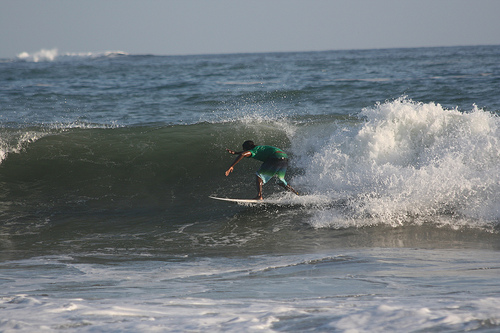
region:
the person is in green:
[232, 137, 306, 199]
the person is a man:
[230, 130, 310, 192]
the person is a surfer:
[227, 136, 339, 206]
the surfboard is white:
[220, 190, 352, 215]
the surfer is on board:
[214, 127, 359, 224]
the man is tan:
[225, 135, 299, 203]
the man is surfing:
[215, 134, 337, 217]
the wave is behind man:
[80, 122, 462, 245]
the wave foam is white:
[283, 120, 485, 225]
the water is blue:
[121, 59, 431, 129]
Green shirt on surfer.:
[243, 147, 288, 163]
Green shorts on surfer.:
[254, 157, 291, 179]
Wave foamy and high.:
[322, 97, 499, 237]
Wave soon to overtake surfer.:
[14, 125, 296, 198]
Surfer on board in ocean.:
[217, 141, 303, 200]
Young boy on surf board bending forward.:
[217, 140, 306, 197]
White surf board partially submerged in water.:
[210, 193, 348, 205]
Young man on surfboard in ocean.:
[204, 137, 349, 221]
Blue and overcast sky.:
[106, 5, 471, 36]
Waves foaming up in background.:
[18, 49, 58, 62]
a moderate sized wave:
[12, 107, 397, 234]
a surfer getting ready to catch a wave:
[202, 123, 340, 231]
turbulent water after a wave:
[282, 86, 498, 237]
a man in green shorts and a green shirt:
[207, 127, 307, 217]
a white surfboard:
[200, 183, 360, 220]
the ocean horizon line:
[26, 26, 498, 73]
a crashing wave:
[110, 78, 495, 238]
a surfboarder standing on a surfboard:
[191, 115, 342, 220]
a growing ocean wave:
[9, 98, 215, 268]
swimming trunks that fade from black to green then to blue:
[250, 148, 304, 188]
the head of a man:
[238, 133, 259, 157]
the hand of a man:
[220, 162, 234, 179]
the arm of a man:
[228, 150, 256, 175]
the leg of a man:
[252, 157, 281, 201]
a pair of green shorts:
[248, 150, 291, 187]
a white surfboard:
[207, 191, 325, 211]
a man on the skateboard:
[218, 132, 306, 208]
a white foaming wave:
[279, 85, 498, 239]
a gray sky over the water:
[0, 0, 497, 65]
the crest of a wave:
[0, 85, 499, 147]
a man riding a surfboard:
[208, 137, 306, 210]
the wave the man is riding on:
[6, 123, 499, 238]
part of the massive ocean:
[13, 250, 498, 330]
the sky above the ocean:
[1, 0, 496, 50]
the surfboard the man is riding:
[207, 187, 252, 202]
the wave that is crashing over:
[290, 105, 475, 215]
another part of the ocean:
[2, 51, 492, 121]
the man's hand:
[217, 165, 232, 176]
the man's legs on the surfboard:
[250, 180, 290, 200]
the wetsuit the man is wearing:
[245, 147, 290, 184]